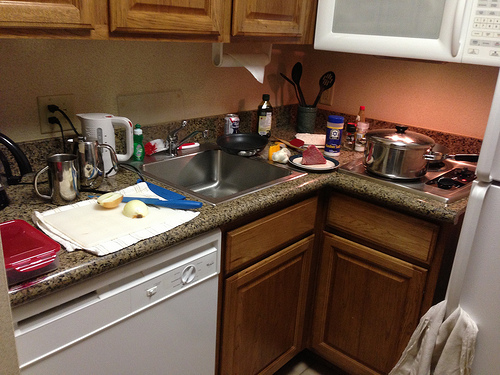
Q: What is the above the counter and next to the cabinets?
A: The microwave.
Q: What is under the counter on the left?
A: The dishwasher.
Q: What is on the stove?
A: A silver pot.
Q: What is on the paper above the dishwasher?
A: An apple.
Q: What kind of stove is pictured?
A: A two-burner over-the-counter stove.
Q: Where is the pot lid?
A: On the pot.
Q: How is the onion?
A: Sliced in half.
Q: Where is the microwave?
A: Over the range.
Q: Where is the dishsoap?
A: Next to the sink.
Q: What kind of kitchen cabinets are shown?
A: Wooden cabinets.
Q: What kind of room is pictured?
A: A kitchen.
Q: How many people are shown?
A: Zero.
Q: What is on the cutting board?
A: Onion.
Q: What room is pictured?
A: Kitchen.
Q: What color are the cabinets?
A: Oak.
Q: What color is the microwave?
A: White.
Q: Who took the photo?
A: Homeowner.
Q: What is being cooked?
A: Dinner.